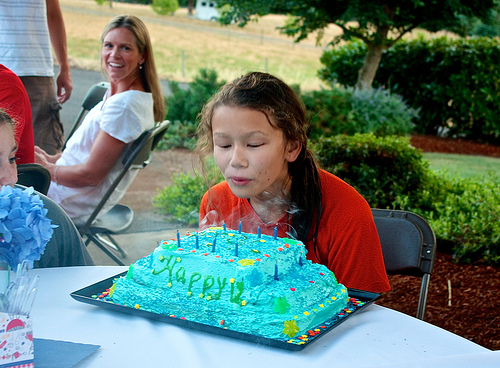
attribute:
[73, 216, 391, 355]
cake — blue, 3 layered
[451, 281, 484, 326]
mulch — brown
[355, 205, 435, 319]
chair — folding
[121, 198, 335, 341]
cake — 3 layered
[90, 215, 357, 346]
cake — birthday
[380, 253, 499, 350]
mulch — red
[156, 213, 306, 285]
candles — birthday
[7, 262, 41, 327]
utensils — plastic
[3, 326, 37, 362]
box — multicolored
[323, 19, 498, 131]
shrubbery — green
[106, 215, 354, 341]
cake — birthday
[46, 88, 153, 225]
shirt — white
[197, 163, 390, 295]
shirt — short-sleeved, orange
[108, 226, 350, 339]
cake — birthday, blue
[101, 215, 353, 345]
frosting — green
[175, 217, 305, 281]
candles — blown-out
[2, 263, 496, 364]
surface — white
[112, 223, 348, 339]
icing — blue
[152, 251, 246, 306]
writing — green